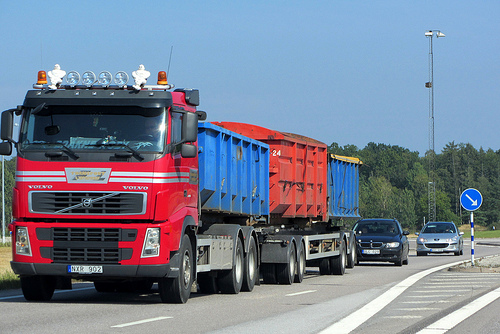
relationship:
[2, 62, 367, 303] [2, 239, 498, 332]
truck on road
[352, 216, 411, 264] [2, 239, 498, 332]
car on road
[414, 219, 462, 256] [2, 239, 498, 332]
car on road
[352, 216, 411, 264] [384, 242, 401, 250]
car has front light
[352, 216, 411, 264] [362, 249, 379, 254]
car has license plate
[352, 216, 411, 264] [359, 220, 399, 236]
car has windshield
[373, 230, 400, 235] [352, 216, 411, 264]
windshield wiper on car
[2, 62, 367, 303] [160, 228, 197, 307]
truck has front wheel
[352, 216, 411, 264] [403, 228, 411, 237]
car has rear view mirror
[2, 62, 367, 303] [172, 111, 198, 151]
truck has rear view mirror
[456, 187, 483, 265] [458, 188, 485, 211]
pole has sign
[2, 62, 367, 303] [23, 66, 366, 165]
truck has roof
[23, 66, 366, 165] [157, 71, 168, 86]
roof has light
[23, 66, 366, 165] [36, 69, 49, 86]
roof has light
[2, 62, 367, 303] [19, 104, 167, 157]
truck has windshield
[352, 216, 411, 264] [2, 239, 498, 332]
car down road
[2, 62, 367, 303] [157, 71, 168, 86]
truck has light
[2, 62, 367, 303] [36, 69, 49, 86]
truck has light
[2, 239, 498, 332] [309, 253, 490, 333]
road has line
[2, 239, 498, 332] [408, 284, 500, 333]
road has line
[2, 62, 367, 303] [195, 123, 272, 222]
truck has cargo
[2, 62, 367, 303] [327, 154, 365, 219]
truck has cargo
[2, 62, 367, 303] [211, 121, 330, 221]
truck has cargo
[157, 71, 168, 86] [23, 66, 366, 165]
light are on roof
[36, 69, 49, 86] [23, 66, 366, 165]
light are on roof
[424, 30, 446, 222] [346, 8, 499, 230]
tower in distance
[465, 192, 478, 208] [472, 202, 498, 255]
arrow ponting southeast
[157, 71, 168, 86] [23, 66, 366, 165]
light on roof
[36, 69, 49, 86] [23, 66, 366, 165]
light on roof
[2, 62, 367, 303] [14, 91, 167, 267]
truck has front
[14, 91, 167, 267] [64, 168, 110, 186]
front has emblem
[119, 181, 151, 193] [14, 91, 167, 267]
volvo in front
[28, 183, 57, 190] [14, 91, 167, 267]
volvo in front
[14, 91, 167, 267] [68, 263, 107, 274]
front has license plate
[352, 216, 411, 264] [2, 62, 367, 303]
car behind truck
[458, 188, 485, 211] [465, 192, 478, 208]
sign has arrow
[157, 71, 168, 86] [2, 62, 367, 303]
light on truck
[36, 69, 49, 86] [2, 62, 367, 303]
light on truck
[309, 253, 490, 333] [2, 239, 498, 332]
line on road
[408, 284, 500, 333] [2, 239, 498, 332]
line on road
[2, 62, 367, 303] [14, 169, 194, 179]
truck has stripe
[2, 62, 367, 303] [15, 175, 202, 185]
truck has stripe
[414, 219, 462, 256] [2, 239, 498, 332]
car down road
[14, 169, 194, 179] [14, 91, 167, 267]
stripe painted on front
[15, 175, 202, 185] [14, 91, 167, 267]
stripe painted on front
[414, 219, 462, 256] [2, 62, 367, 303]
car behind truck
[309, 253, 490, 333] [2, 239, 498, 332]
line painted on road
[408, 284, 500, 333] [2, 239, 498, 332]
line painted on road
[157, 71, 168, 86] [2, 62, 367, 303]
light on top of truck